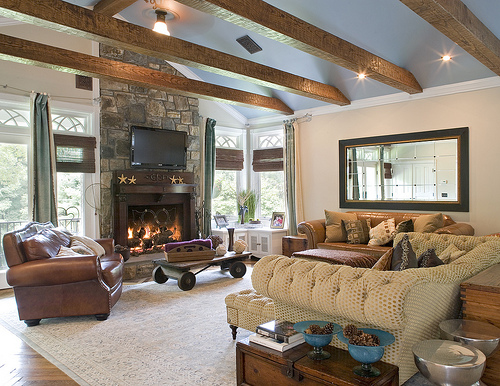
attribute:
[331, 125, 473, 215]
mirror — large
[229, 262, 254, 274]
wheel — black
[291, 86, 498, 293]
wall — white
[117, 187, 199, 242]
fireplace — large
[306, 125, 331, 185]
wall — white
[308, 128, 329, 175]
wall — white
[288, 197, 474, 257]
couch — brown, leather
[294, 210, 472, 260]
couch — brown, leather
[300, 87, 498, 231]
wall — white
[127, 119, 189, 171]
tv — flat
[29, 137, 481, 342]
living room — airy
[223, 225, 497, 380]
couch — white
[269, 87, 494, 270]
wall — white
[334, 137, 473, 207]
mirror — rectangular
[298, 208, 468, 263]
sofa — brown, leather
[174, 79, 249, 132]
wall — white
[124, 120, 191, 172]
tv — black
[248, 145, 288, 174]
shade — brown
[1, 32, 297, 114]
beam — wooden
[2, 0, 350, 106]
beam — wooden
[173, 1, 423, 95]
beam — wooden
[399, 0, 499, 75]
beam — wooden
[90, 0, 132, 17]
beam — wooden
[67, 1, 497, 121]
ceiling — blue